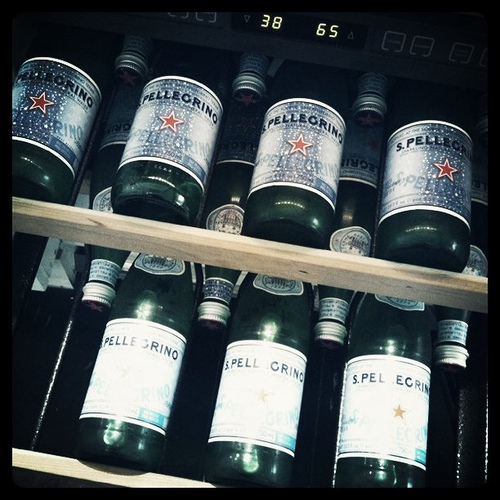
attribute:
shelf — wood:
[24, 417, 128, 499]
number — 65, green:
[315, 24, 340, 38]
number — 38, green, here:
[260, 14, 285, 30]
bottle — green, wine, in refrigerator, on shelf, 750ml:
[13, 1, 111, 208]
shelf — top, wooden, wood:
[12, 198, 489, 314]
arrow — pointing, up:
[346, 28, 357, 42]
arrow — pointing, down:
[244, 12, 255, 22]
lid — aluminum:
[199, 300, 233, 327]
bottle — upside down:
[197, 265, 242, 327]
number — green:
[260, 14, 270, 30]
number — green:
[272, 15, 284, 31]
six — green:
[318, 22, 328, 36]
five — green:
[329, 21, 341, 39]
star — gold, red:
[162, 111, 183, 131]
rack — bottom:
[8, 446, 215, 488]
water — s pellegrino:
[203, 105, 266, 236]